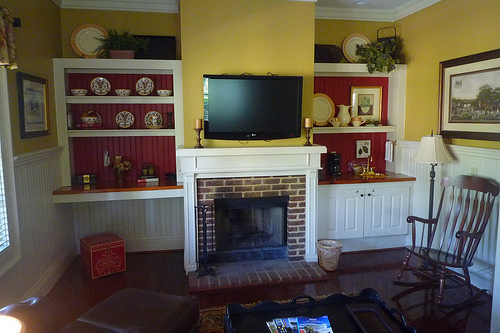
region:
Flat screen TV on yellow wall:
[194, 59, 305, 141]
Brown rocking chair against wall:
[404, 167, 484, 318]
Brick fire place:
[194, 180, 310, 267]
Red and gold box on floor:
[77, 222, 133, 287]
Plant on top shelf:
[99, 28, 149, 62]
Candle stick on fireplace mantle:
[188, 104, 210, 149]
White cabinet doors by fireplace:
[317, 184, 412, 236]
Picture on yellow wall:
[11, 60, 57, 141]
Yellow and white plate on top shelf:
[67, 16, 108, 61]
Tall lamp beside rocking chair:
[414, 128, 451, 270]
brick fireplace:
[184, 174, 332, 286]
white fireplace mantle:
[171, 141, 330, 175]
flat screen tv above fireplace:
[200, 75, 303, 140]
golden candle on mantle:
[191, 117, 205, 151]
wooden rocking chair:
[392, 172, 499, 307]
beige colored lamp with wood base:
[414, 130, 457, 216]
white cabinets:
[312, 181, 407, 238]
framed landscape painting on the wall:
[439, 43, 498, 135]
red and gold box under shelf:
[80, 233, 131, 277]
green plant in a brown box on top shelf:
[93, 27, 153, 57]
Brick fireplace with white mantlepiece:
[169, 139, 344, 299]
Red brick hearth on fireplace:
[185, 245, 327, 299]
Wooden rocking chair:
[390, 171, 492, 313]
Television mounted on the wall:
[192, 67, 310, 142]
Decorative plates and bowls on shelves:
[58, 57, 187, 138]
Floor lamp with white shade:
[404, 126, 461, 282]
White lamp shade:
[410, 133, 460, 165]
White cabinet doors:
[310, 176, 421, 251]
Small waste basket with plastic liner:
[317, 231, 344, 273]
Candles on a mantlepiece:
[183, 115, 321, 145]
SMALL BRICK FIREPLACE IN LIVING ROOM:
[177, 139, 317, 276]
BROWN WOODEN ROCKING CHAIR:
[410, 163, 480, 278]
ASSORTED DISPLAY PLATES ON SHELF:
[63, 72, 168, 141]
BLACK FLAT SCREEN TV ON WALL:
[210, 71, 295, 141]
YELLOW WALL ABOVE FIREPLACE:
[183, 4, 305, 144]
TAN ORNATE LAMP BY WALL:
[420, 124, 456, 264]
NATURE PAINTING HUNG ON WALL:
[423, 52, 498, 119]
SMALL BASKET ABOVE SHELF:
[365, 16, 405, 78]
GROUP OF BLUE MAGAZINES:
[265, 301, 323, 331]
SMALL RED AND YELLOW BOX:
[68, 218, 139, 278]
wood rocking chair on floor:
[366, 161, 498, 322]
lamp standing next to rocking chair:
[407, 129, 485, 298]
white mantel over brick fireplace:
[172, 139, 339, 302]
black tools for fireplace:
[180, 199, 244, 288]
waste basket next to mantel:
[302, 226, 371, 300]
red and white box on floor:
[70, 222, 152, 286]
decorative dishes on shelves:
[68, 68, 187, 161]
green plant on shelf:
[349, 27, 415, 81]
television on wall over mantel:
[179, 43, 324, 178]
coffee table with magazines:
[196, 288, 416, 331]